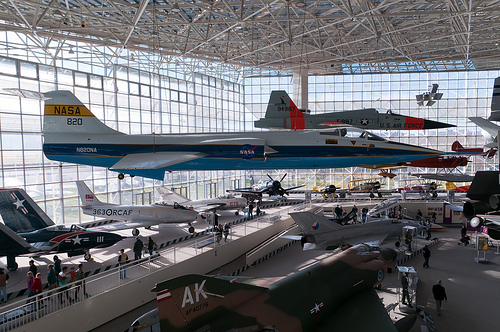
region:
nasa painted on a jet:
[40, 99, 87, 122]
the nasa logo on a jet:
[237, 135, 259, 162]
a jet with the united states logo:
[355, 111, 375, 124]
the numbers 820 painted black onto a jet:
[58, 109, 84, 127]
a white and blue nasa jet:
[25, 70, 439, 184]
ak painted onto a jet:
[178, 267, 210, 306]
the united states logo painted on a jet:
[309, 290, 327, 314]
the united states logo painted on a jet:
[65, 230, 89, 250]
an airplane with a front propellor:
[228, 172, 304, 200]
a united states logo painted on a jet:
[8, 190, 33, 219]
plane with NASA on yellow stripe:
[33, 86, 468, 184]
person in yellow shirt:
[111, 248, 132, 282]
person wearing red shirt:
[27, 272, 47, 317]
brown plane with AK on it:
[145, 240, 405, 330]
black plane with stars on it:
[2, 189, 132, 261]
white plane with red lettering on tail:
[75, 181, 203, 236]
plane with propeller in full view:
[249, 167, 309, 205]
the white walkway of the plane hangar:
[3, 206, 308, 331]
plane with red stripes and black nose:
[248, 86, 455, 138]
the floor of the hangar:
[0, 191, 499, 328]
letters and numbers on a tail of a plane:
[37, 90, 109, 129]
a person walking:
[424, 265, 456, 325]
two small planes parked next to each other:
[74, 177, 255, 232]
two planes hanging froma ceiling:
[20, 71, 480, 187]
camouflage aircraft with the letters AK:
[148, 234, 410, 323]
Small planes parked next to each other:
[3, 172, 319, 268]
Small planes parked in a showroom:
[10, 174, 427, 265]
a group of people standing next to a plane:
[9, 193, 91, 310]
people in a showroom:
[78, 174, 267, 268]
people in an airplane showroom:
[9, 177, 265, 314]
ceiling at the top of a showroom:
[85, 13, 469, 83]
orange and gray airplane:
[235, 82, 466, 127]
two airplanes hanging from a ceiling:
[32, 81, 472, 181]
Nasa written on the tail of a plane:
[34, 83, 115, 164]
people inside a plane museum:
[5, 181, 298, 294]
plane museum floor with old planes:
[164, 200, 458, 323]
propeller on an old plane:
[253, 168, 295, 198]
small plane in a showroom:
[5, 188, 121, 257]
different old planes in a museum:
[78, 169, 285, 231]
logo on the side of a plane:
[299, 300, 333, 320]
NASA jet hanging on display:
[42, 80, 448, 181]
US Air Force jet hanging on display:
[253, 85, 454, 133]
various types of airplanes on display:
[0, 175, 498, 330]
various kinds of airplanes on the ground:
[2, 173, 497, 328]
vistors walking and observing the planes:
[5, 245, 160, 305]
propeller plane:
[222, 170, 304, 202]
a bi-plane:
[342, 172, 388, 198]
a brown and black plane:
[156, 240, 416, 325]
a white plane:
[76, 180, 201, 222]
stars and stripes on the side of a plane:
[63, 233, 94, 253]